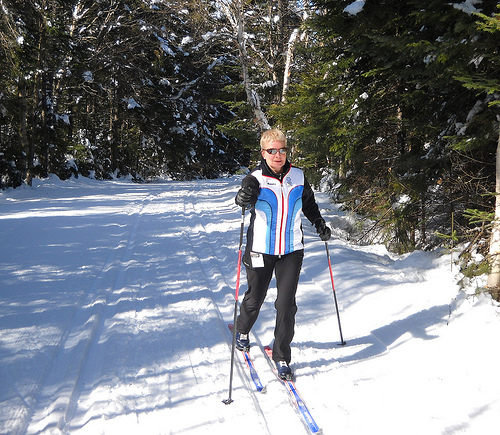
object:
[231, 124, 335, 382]
woman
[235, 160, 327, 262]
coat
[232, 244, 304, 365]
pant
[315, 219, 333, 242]
gloves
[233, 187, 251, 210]
gloves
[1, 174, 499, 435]
snow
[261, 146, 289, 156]
goggles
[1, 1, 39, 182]
trees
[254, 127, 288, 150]
hair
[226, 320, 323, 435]
skiis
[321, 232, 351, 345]
stick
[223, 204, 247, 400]
stick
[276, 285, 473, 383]
shadow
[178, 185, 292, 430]
tracks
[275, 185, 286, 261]
zipper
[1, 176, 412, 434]
shadow